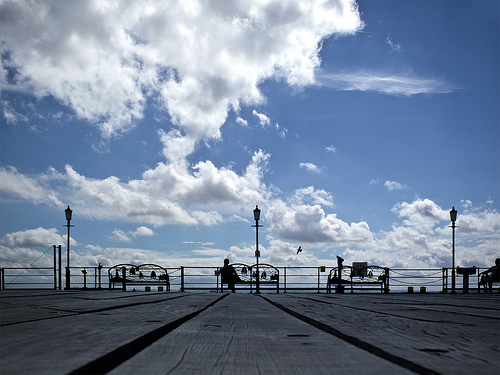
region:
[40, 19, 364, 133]
big bright white cloud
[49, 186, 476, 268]
lights in the background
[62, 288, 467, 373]
old brown wooden floor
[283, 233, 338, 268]
bird flying in background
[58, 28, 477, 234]
bright clear blue sky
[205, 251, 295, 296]
man sitting down on bench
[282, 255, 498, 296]
spare benches on the dock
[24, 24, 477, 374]
nice big dock in background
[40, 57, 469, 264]
lots of clouds in background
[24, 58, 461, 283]
a clear and beautiful sight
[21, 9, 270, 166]
The clouds are white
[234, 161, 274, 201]
a cloud in the sky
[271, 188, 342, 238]
clouds in the sky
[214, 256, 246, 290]
a person sitting on a bench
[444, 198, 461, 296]
a lighy pole on a wooden platform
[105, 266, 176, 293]
a bench on a platform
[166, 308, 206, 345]
the crack between boards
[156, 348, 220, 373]
the grains in a piece of wood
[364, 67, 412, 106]
a cloud in the sky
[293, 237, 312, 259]
a bird in the sky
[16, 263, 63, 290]
a pole railing on a platform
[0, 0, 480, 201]
blue sky and puffy white clouds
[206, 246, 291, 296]
person sitting on a bench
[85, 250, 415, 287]
three benches side by side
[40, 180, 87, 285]
light post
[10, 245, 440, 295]
fence at the end of the boardwalk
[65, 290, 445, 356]
wooden boards form a walkway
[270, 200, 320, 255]
bird flying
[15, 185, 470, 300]
three light posts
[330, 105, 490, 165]
blue sky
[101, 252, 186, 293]
intricate design on a bench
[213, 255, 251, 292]
Person sitting on a bench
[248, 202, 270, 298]
Light pole on a pier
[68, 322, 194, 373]
Gap between two wood planks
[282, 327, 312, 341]
Hole in a wooden plank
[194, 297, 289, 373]
Wooden plank on a pier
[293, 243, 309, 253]
Bird flying in the sky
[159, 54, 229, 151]
White cloud in the sky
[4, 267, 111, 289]
Fence at a pier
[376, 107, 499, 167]
Cloudless blue sky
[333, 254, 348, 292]
Binoculars on a pole at a pier